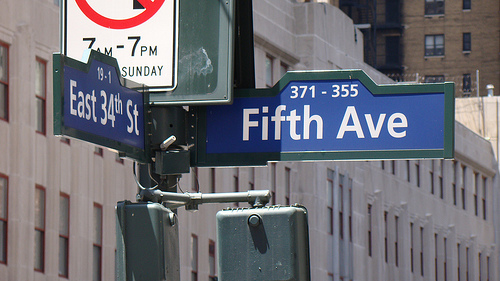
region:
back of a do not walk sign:
[215, 204, 310, 279]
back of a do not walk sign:
[114, 198, 176, 279]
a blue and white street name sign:
[194, 68, 456, 160]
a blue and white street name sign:
[44, 51, 152, 161]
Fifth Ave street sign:
[194, 75, 446, 156]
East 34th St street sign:
[56, 63, 143, 143]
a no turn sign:
[62, 0, 179, 90]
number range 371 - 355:
[278, 81, 366, 101]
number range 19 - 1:
[91, 60, 116, 84]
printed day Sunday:
[116, 61, 163, 81]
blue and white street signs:
[60, 45, 440, 177]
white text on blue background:
[227, 77, 418, 152]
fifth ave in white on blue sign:
[237, 102, 419, 140]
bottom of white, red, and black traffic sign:
[61, 2, 178, 89]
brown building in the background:
[365, 1, 497, 95]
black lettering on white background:
[65, 21, 168, 83]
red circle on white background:
[76, 2, 164, 32]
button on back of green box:
[241, 207, 263, 227]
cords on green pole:
[123, 114, 198, 200]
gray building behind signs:
[3, 7, 495, 280]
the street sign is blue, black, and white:
[163, 60, 460, 188]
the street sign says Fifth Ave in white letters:
[172, 31, 471, 228]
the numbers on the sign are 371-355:
[267, 64, 381, 104]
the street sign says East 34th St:
[37, 35, 160, 167]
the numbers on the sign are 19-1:
[64, 40, 143, 97]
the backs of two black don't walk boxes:
[96, 153, 301, 278]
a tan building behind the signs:
[7, 4, 497, 279]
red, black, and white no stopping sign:
[55, 2, 181, 102]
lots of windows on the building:
[5, 31, 491, 279]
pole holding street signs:
[102, 29, 217, 279]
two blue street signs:
[47, 46, 442, 160]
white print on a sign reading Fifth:
[237, 104, 325, 142]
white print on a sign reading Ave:
[334, 104, 409, 142]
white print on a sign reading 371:
[288, 83, 316, 100]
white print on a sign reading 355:
[330, 81, 360, 99]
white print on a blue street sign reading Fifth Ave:
[234, 101, 408, 143]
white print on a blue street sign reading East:
[68, 76, 100, 120]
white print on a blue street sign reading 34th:
[98, 89, 123, 127]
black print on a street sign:
[125, 32, 160, 60]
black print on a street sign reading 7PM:
[124, 35, 159, 59]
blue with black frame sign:
[203, 59, 473, 166]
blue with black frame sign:
[41, 43, 163, 158]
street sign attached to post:
[216, 48, 463, 173]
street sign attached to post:
[46, 42, 160, 159]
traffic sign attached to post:
[63, 2, 190, 79]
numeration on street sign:
[291, 82, 365, 101]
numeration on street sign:
[97, 63, 119, 84]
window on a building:
[409, 23, 461, 62]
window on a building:
[320, 173, 344, 240]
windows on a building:
[403, 213, 430, 273]